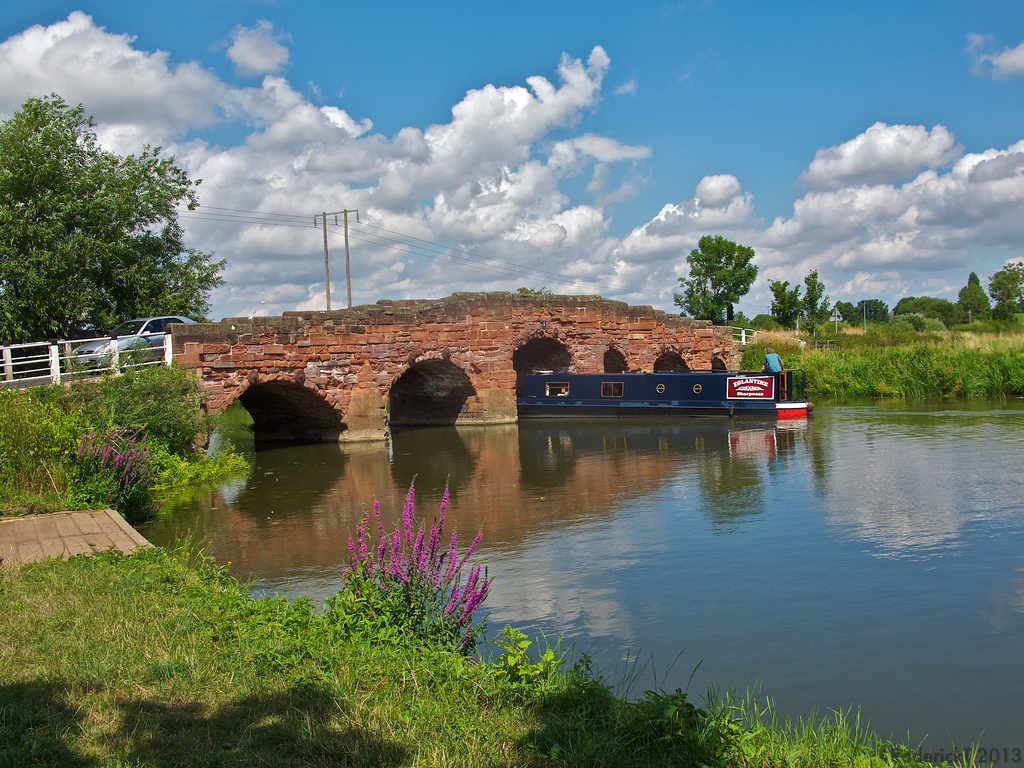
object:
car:
[69, 315, 196, 370]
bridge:
[167, 286, 752, 451]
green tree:
[5, 213, 40, 263]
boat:
[521, 368, 812, 412]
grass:
[5, 680, 122, 764]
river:
[131, 408, 1023, 758]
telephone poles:
[341, 209, 353, 307]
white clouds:
[812, 122, 958, 171]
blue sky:
[0, 2, 1021, 307]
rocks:
[374, 362, 395, 374]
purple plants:
[445, 563, 495, 630]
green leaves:
[109, 211, 125, 224]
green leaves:
[121, 263, 147, 285]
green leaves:
[47, 219, 82, 250]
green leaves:
[87, 291, 113, 321]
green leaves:
[149, 157, 182, 195]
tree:
[2, 86, 178, 332]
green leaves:
[708, 245, 720, 255]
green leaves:
[738, 266, 754, 277]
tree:
[674, 234, 760, 322]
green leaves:
[787, 294, 802, 313]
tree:
[770, 278, 807, 324]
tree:
[857, 297, 888, 323]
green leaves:
[878, 312, 887, 321]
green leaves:
[986, 320, 1006, 332]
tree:
[959, 270, 992, 322]